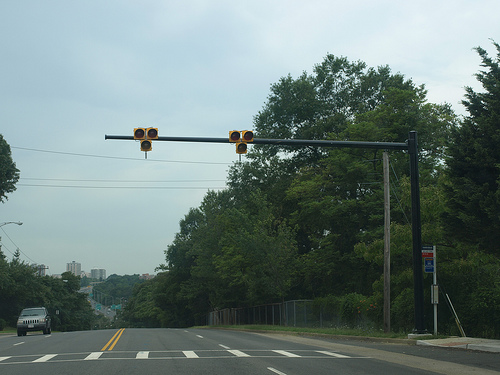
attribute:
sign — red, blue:
[418, 244, 434, 259]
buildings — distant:
[88, 265, 107, 280]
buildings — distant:
[63, 256, 83, 274]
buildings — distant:
[141, 270, 153, 280]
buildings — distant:
[34, 261, 46, 280]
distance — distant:
[12, 227, 165, 281]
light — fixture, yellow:
[134, 126, 159, 153]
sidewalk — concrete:
[418, 330, 498, 352]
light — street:
[134, 125, 160, 156]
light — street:
[224, 128, 255, 156]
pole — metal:
[102, 125, 432, 337]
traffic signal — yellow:
[229, 127, 254, 157]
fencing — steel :
[206, 300, 309, 327]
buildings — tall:
[42, 253, 107, 290]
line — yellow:
[102, 327, 126, 352]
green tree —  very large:
[228, 56, 461, 328]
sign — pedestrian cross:
[1, 346, 371, 368]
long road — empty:
[2, 287, 496, 372]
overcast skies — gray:
[2, 1, 499, 283]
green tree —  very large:
[187, 176, 297, 332]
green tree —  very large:
[442, 41, 498, 261]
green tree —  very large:
[287, 82, 434, 327]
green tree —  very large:
[152, 201, 227, 323]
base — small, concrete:
[416, 329, 451, 344]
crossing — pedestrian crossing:
[0, 345, 364, 374]